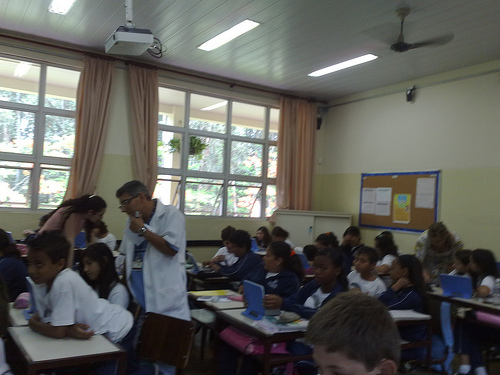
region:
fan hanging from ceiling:
[328, 8, 476, 71]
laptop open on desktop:
[235, 262, 323, 329]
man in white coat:
[116, 171, 208, 351]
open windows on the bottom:
[159, 76, 301, 217]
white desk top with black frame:
[205, 294, 330, 367]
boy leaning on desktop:
[22, 223, 149, 348]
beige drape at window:
[48, 50, 121, 228]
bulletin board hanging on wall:
[346, 151, 478, 274]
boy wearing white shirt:
[22, 230, 135, 338]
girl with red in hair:
[240, 227, 309, 320]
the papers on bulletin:
[364, 180, 435, 227]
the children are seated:
[223, 213, 457, 313]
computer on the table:
[237, 280, 293, 345]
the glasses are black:
[119, 199, 137, 207]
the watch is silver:
[136, 224, 150, 238]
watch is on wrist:
[133, 225, 148, 240]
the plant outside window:
[158, 106, 273, 218]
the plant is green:
[169, 129, 206, 156]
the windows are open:
[160, 177, 285, 219]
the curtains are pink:
[275, 105, 320, 215]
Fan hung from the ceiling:
[362, 6, 461, 60]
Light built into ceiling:
[191, 8, 264, 66]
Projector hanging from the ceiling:
[87, 21, 165, 61]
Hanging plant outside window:
[167, 118, 212, 162]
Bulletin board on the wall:
[360, 166, 443, 236]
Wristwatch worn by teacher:
[130, 219, 150, 241]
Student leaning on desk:
[20, 223, 138, 358]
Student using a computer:
[240, 245, 347, 330]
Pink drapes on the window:
[272, 91, 315, 219]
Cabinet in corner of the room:
[274, 205, 362, 251]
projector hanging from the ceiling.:
[114, 20, 149, 50]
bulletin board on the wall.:
[344, 162, 439, 223]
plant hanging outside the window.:
[181, 141, 207, 153]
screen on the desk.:
[239, 280, 265, 314]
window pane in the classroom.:
[228, 148, 258, 169]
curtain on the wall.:
[135, 87, 152, 169]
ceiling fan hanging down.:
[378, 20, 438, 58]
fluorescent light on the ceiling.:
[302, 47, 374, 100]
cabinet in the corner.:
[285, 210, 340, 236]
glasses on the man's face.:
[114, 192, 137, 209]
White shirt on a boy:
[24, 272, 149, 337]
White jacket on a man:
[115, 206, 235, 340]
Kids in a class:
[222, 158, 464, 331]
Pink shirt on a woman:
[20, 177, 112, 259]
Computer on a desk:
[234, 274, 288, 321]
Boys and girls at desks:
[326, 235, 441, 301]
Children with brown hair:
[209, 196, 406, 299]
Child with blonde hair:
[292, 286, 429, 356]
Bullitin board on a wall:
[354, 154, 456, 246]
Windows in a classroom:
[142, 98, 299, 227]